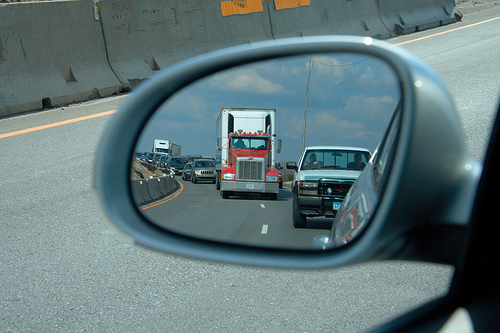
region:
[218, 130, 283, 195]
red truck behind car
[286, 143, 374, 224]
white truck behind car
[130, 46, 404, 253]
side view mirror on car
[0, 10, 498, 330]
road is next to car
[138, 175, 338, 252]
road underneath truck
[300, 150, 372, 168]
windshield on white truck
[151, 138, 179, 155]
white truck behind car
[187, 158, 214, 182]
car behind red truck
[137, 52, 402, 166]
blue sky behind red truck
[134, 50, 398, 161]
blue sky behind white truck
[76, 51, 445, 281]
a side mirror of a car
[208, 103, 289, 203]
a red semi truck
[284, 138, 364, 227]
a white pick up truck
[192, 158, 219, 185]
a gold suv car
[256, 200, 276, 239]
white paint stripes on the road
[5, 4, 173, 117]
a jersey barrier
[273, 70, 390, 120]
the cloudy sky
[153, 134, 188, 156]
a white semi truck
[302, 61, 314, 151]
a pole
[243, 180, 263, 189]
the licence plate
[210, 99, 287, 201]
red and white truck in the mirror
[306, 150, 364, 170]
two people in the truck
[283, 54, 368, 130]
electrical wire on the pole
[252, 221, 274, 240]
white line on the road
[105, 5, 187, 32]
graffati on the cement wall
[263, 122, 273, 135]
pipe stack on the truck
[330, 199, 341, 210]
license plate on the truck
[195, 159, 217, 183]
gray vehicle on the road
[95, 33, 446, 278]
mirror on the car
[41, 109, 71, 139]
yellow line on the road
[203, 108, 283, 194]
large semi truck on road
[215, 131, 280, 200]
red front of semi truck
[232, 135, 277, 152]
front window of semi truck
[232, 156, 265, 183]
metal radiator on front of truck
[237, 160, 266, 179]
silver metal grill on truck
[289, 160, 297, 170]
black side view mirror on truck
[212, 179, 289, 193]
silver front bumper on truck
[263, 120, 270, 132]
smoke stack on top of truck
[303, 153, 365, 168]
two people sitting in truck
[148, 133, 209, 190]
line of cars in traffic